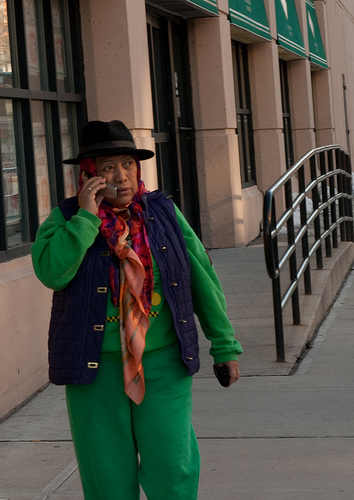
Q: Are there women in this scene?
A: Yes, there is a woman.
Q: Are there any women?
A: Yes, there is a woman.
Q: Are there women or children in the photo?
A: Yes, there is a woman.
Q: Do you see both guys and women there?
A: No, there is a woman but no guys.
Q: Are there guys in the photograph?
A: No, there are no guys.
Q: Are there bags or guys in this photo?
A: No, there are no guys or bags.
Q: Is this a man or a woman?
A: This is a woman.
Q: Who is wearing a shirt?
A: The woman is wearing a shirt.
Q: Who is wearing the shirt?
A: The woman is wearing a shirt.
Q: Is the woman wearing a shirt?
A: Yes, the woman is wearing a shirt.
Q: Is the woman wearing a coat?
A: No, the woman is wearing a shirt.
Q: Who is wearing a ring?
A: The woman is wearing a ring.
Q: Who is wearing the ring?
A: The woman is wearing a ring.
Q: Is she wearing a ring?
A: Yes, the woman is wearing a ring.